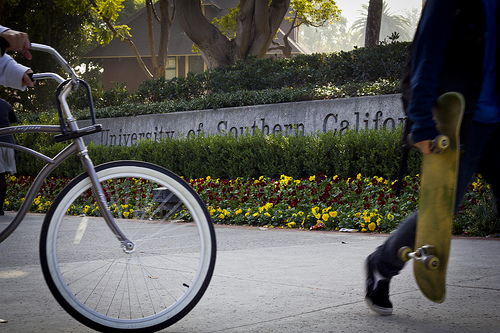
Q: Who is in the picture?
A: Two men.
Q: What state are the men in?
A: California.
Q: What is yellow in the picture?
A: Flowers.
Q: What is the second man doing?
A: Riding a bike.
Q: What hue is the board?
A: Yellow.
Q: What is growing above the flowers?
A: Bushes.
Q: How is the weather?
A: Overcast.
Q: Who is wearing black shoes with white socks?
A: The person carrying a skateboard.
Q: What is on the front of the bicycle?
A: A black and white wheel.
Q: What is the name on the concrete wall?
A: University of Southern California.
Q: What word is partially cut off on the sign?
A: California.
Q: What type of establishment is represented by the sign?
A: A university.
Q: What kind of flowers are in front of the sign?
A: Small yellow flowers.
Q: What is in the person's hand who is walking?
A: A skateboard.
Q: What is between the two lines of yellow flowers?
A: Red flowers.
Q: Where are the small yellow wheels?
A: Bottom of the skateboard.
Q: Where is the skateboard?
A: In the hand of a man.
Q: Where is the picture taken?
A: At a University in California.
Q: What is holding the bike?
A: Two hands are holding it.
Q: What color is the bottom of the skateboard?
A: Yellow.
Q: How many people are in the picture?
A: Two.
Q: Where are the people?
A: At the University of Southern California.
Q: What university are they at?
A: The University of Southern California.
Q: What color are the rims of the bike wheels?
A: White.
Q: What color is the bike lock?
A: Black.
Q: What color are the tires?
A: Black.